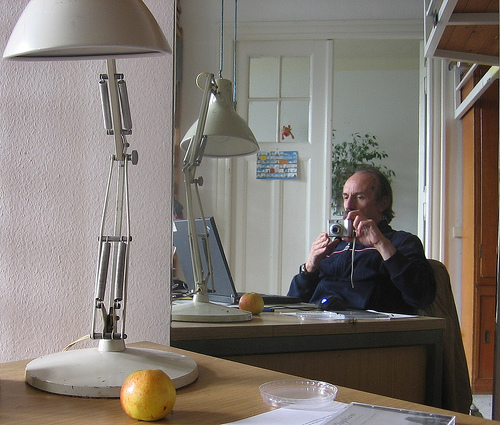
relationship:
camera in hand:
[327, 220, 351, 239] [307, 233, 338, 268]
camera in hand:
[327, 220, 351, 239] [344, 212, 383, 251]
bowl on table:
[259, 380, 338, 406] [0, 339, 499, 423]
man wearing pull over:
[290, 169, 440, 308] [288, 222, 432, 312]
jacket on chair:
[418, 258, 473, 415] [420, 258, 476, 411]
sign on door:
[256, 153, 299, 182] [233, 41, 326, 297]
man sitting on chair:
[290, 169, 440, 308] [420, 258, 476, 411]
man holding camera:
[290, 169, 440, 308] [327, 220, 351, 239]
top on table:
[259, 380, 338, 406] [0, 339, 499, 423]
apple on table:
[120, 368, 179, 422] [0, 339, 499, 423]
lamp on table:
[3, 0, 199, 398] [0, 339, 499, 423]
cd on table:
[328, 401, 461, 424] [0, 339, 499, 423]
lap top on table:
[172, 218, 299, 306] [0, 339, 499, 423]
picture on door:
[256, 153, 299, 182] [233, 41, 326, 297]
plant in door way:
[330, 132, 392, 239] [236, 44, 422, 315]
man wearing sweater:
[290, 169, 440, 308] [288, 222, 432, 312]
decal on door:
[282, 125, 296, 142] [233, 41, 326, 297]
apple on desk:
[120, 368, 179, 422] [0, 339, 499, 423]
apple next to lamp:
[120, 368, 179, 422] [3, 0, 199, 398]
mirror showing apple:
[169, 0, 498, 418] [241, 293, 264, 312]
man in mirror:
[290, 169, 440, 308] [169, 0, 498, 418]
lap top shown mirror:
[172, 218, 299, 306] [169, 0, 498, 418]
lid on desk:
[259, 380, 338, 406] [0, 339, 499, 423]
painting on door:
[256, 153, 299, 182] [233, 41, 326, 297]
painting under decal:
[256, 153, 299, 182] [282, 125, 296, 142]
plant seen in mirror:
[330, 132, 392, 239] [169, 0, 498, 418]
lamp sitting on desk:
[3, 0, 199, 398] [0, 339, 499, 423]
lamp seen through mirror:
[3, 0, 199, 398] [169, 0, 498, 418]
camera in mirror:
[327, 220, 351, 239] [169, 0, 498, 418]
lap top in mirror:
[172, 218, 299, 306] [169, 0, 498, 418]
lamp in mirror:
[3, 0, 199, 398] [169, 0, 498, 418]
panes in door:
[247, 57, 310, 141] [233, 41, 326, 297]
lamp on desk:
[3, 0, 199, 398] [0, 339, 499, 423]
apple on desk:
[241, 293, 264, 312] [172, 298, 449, 408]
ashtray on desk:
[259, 380, 338, 406] [0, 339, 499, 423]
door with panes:
[233, 41, 326, 297] [247, 57, 310, 141]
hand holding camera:
[307, 233, 338, 268] [327, 220, 351, 239]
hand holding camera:
[344, 212, 383, 251] [327, 220, 351, 239]